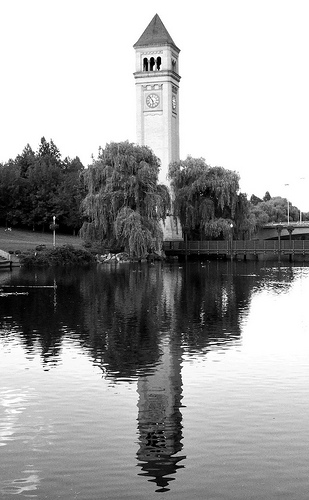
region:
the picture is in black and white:
[51, 0, 308, 475]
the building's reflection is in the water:
[110, 315, 221, 488]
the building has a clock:
[129, 73, 258, 166]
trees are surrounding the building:
[8, 126, 308, 273]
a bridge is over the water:
[152, 226, 303, 276]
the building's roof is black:
[121, 9, 196, 50]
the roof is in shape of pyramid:
[121, 2, 197, 86]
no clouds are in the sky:
[15, 39, 300, 170]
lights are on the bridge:
[203, 213, 304, 252]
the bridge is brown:
[171, 229, 304, 270]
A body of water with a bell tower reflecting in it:
[39, 360, 222, 492]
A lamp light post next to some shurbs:
[28, 214, 95, 274]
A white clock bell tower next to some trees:
[128, 3, 187, 260]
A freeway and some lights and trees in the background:
[260, 215, 306, 263]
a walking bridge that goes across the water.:
[162, 240, 307, 260]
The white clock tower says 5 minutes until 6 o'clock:
[137, 86, 162, 120]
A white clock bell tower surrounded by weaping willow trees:
[88, 10, 257, 271]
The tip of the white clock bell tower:
[134, 7, 182, 77]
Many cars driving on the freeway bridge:
[259, 203, 308, 282]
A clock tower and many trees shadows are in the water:
[9, 8, 300, 366]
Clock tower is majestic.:
[130, 8, 189, 244]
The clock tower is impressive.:
[132, 6, 184, 244]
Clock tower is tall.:
[130, 9, 188, 243]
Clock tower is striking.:
[130, 12, 182, 255]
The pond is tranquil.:
[0, 257, 308, 497]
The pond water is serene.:
[1, 260, 307, 498]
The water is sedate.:
[0, 254, 308, 498]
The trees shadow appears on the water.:
[1, 263, 301, 385]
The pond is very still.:
[0, 263, 308, 498]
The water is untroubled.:
[1, 263, 308, 498]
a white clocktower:
[130, 6, 186, 253]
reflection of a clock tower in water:
[125, 256, 191, 492]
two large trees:
[71, 145, 254, 269]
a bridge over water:
[130, 216, 308, 269]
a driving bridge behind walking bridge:
[241, 169, 308, 237]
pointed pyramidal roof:
[121, 9, 185, 52]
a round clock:
[142, 91, 162, 111]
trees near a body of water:
[3, 122, 90, 242]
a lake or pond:
[2, 249, 307, 447]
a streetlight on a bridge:
[281, 178, 292, 230]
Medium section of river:
[38, 315, 213, 430]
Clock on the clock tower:
[142, 94, 163, 110]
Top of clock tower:
[143, 9, 168, 44]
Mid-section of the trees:
[39, 176, 62, 200]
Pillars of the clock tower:
[145, 60, 152, 70]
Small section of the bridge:
[294, 224, 308, 233]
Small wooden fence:
[0, 257, 17, 270]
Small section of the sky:
[64, 115, 99, 138]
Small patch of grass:
[21, 233, 32, 242]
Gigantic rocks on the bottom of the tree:
[105, 252, 117, 261]